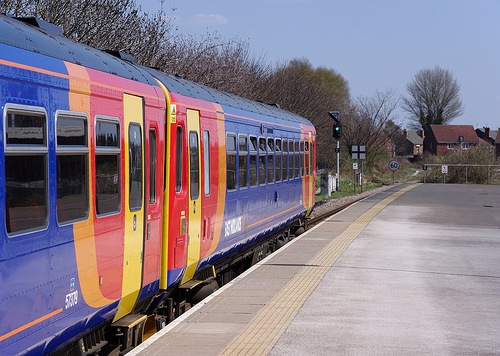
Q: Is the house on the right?
A: Yes, the house is on the right of the image.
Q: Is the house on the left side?
A: No, the house is on the right of the image.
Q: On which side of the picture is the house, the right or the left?
A: The house is on the right of the image.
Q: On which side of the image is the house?
A: The house is on the right of the image.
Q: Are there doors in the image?
A: Yes, there is a door.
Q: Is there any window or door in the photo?
A: Yes, there is a door.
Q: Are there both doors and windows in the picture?
A: Yes, there are both a door and a window.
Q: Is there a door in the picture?
A: Yes, there is a door.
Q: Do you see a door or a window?
A: Yes, there is a door.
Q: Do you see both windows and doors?
A: Yes, there are both a door and a window.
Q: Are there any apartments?
A: No, there are no apartments.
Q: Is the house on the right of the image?
A: Yes, the house is on the right of the image.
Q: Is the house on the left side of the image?
A: No, the house is on the right of the image.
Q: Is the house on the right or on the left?
A: The house is on the right of the image.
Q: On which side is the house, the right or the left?
A: The house is on the right of the image.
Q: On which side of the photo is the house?
A: The house is on the right of the image.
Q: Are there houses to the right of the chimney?
A: Yes, there is a house to the right of the chimney.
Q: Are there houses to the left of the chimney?
A: No, the house is to the right of the chimney.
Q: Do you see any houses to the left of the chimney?
A: No, the house is to the right of the chimney.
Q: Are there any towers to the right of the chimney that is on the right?
A: No, there is a house to the right of the chimney.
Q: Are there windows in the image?
A: Yes, there is a window.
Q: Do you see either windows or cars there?
A: Yes, there is a window.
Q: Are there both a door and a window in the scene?
A: Yes, there are both a window and a door.